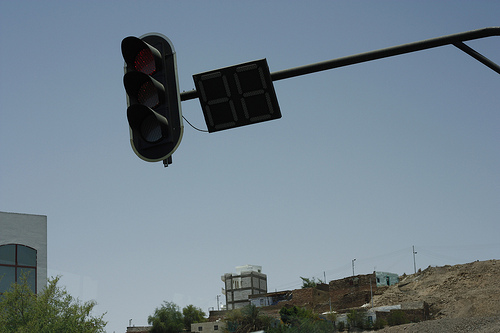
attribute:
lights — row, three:
[93, 20, 236, 246]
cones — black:
[108, 18, 169, 176]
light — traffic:
[106, 34, 190, 205]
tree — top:
[19, 284, 87, 319]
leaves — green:
[11, 263, 75, 331]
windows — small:
[2, 228, 55, 308]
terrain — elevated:
[208, 276, 498, 330]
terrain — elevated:
[224, 264, 498, 327]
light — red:
[111, 33, 171, 71]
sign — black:
[197, 58, 285, 130]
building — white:
[219, 270, 272, 310]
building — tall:
[218, 267, 275, 313]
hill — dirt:
[274, 279, 491, 319]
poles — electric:
[347, 246, 426, 275]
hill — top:
[224, 270, 409, 325]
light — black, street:
[116, 30, 191, 169]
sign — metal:
[194, 57, 279, 123]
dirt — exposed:
[418, 270, 493, 309]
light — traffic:
[114, 27, 194, 161]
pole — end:
[176, 50, 376, 106]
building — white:
[0, 213, 53, 315]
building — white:
[222, 270, 264, 306]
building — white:
[5, 210, 48, 310]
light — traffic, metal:
[119, 32, 186, 174]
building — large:
[218, 253, 284, 330]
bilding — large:
[0, 183, 72, 329]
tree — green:
[0, 253, 151, 327]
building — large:
[9, 178, 91, 330]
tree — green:
[0, 265, 152, 330]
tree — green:
[1, 260, 177, 330]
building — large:
[3, 188, 129, 330]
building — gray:
[0, 177, 60, 327]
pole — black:
[189, 13, 499, 124]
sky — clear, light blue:
[12, 10, 498, 297]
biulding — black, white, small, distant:
[199, 254, 278, 330]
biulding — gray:
[0, 200, 64, 310]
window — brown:
[0, 231, 40, 318]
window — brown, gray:
[0, 235, 50, 305]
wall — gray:
[0, 185, 73, 303]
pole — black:
[272, 10, 498, 90]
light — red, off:
[113, 35, 174, 86]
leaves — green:
[0, 250, 179, 327]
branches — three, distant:
[123, 267, 207, 330]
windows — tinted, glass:
[3, 245, 43, 299]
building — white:
[1, 212, 53, 324]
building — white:
[0, 208, 45, 292]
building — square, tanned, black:
[216, 266, 266, 313]